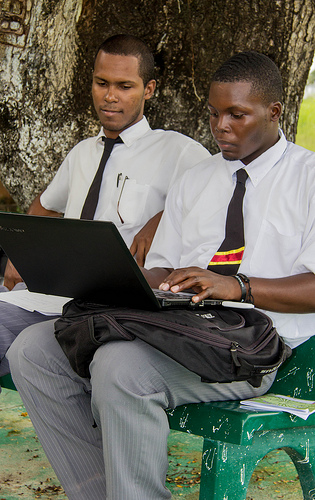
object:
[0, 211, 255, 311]
computer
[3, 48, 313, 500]
guy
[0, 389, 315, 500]
ground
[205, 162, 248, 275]
tie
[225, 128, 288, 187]
collar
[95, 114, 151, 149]
collar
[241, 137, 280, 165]
neck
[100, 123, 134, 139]
neck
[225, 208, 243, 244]
darker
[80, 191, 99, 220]
darker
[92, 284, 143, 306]
darker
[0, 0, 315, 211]
tree trunk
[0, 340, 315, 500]
green bench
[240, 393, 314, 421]
book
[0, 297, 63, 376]
bench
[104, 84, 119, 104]
nose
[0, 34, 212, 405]
guy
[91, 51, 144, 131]
face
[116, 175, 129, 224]
glasses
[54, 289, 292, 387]
backpack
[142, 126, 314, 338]
shirt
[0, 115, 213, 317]
shirt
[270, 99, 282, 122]
left ear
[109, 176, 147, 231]
pocket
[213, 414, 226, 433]
spots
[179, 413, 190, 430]
spots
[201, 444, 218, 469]
spots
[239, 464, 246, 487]
spots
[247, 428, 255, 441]
spots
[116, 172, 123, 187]
pen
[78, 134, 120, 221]
tie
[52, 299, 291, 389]
lap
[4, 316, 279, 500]
bench